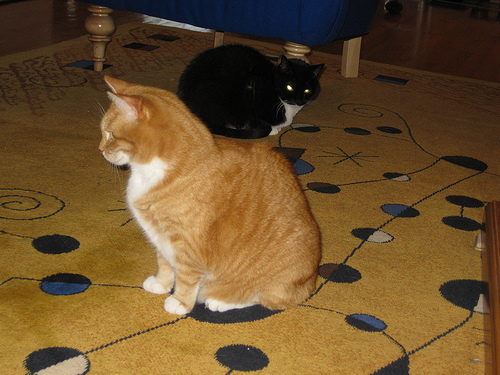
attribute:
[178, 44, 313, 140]
cat — black, sitting, orange, curled, striped, brown, tucked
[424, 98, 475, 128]
floor — tan, brown, orange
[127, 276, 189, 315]
paws — white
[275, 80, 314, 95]
eyes — yellow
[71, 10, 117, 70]
legs — wooden, curved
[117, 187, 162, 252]
chest — white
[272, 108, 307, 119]
neck — white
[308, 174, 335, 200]
circle — blue, white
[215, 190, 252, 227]
stripes — brown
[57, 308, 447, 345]
directions — different